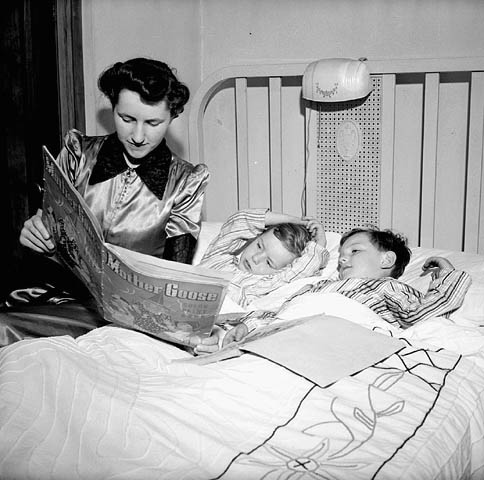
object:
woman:
[18, 57, 235, 348]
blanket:
[0, 292, 483, 480]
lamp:
[301, 57, 373, 102]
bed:
[188, 72, 482, 254]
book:
[41, 144, 232, 348]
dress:
[0, 129, 210, 345]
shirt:
[211, 211, 321, 316]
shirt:
[290, 276, 468, 319]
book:
[172, 312, 406, 388]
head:
[271, 224, 309, 258]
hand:
[301, 215, 321, 237]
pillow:
[192, 221, 484, 331]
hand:
[19, 207, 57, 254]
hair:
[96, 58, 189, 119]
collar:
[88, 133, 172, 202]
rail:
[234, 76, 250, 211]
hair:
[340, 224, 412, 279]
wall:
[80, 0, 484, 257]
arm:
[384, 268, 472, 320]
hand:
[422, 256, 443, 273]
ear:
[381, 251, 397, 269]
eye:
[352, 249, 361, 254]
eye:
[257, 243, 262, 249]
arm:
[208, 208, 300, 253]